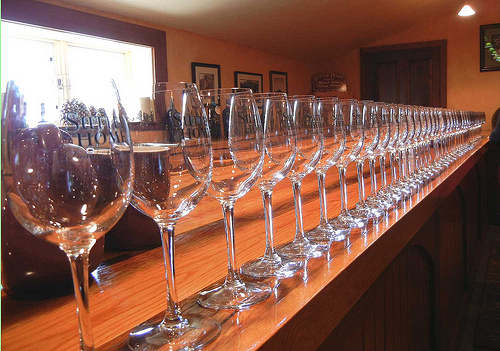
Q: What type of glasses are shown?
A: Wine.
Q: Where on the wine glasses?
A: On the bar.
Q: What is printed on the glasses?
A: Sutter Home.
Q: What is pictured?
A: A row of wine glasses.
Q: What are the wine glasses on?
A: A counter.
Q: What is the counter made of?
A: Wood.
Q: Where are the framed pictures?
A: On the wall.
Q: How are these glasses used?
A: To drink wine from.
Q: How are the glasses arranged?
A: In a straight line.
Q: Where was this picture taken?
A: A bar.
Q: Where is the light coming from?
A: The ceiling light and through the window.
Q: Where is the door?
A: In the back of the room.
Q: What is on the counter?
A: Wine glasses.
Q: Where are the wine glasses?
A: On the counter.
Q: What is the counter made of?
A: Wood.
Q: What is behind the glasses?
A: Window.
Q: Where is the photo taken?
A: Bar.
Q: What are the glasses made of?
A: Glass.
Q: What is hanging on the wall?
A: Pictures.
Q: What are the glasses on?
A: On a bar.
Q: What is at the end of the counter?
A: A door.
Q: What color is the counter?
A: Brown.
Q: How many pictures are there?
A: 4.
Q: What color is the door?
A: Brown.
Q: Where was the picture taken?
A: In a bar.